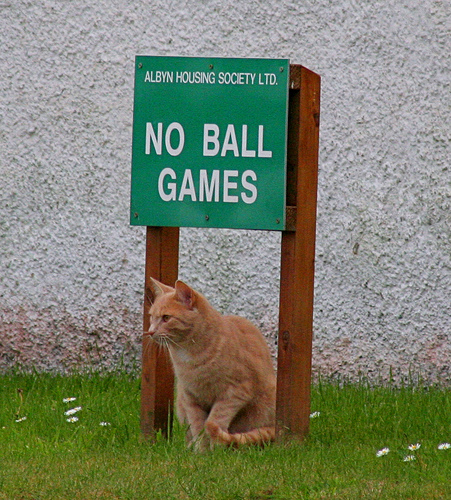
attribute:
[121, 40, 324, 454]
poles — wooden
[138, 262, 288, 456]
cat — under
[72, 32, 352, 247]
sign — green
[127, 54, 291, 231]
sign — green, white, on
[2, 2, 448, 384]
wall — rough, gray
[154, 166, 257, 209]
lettering — on